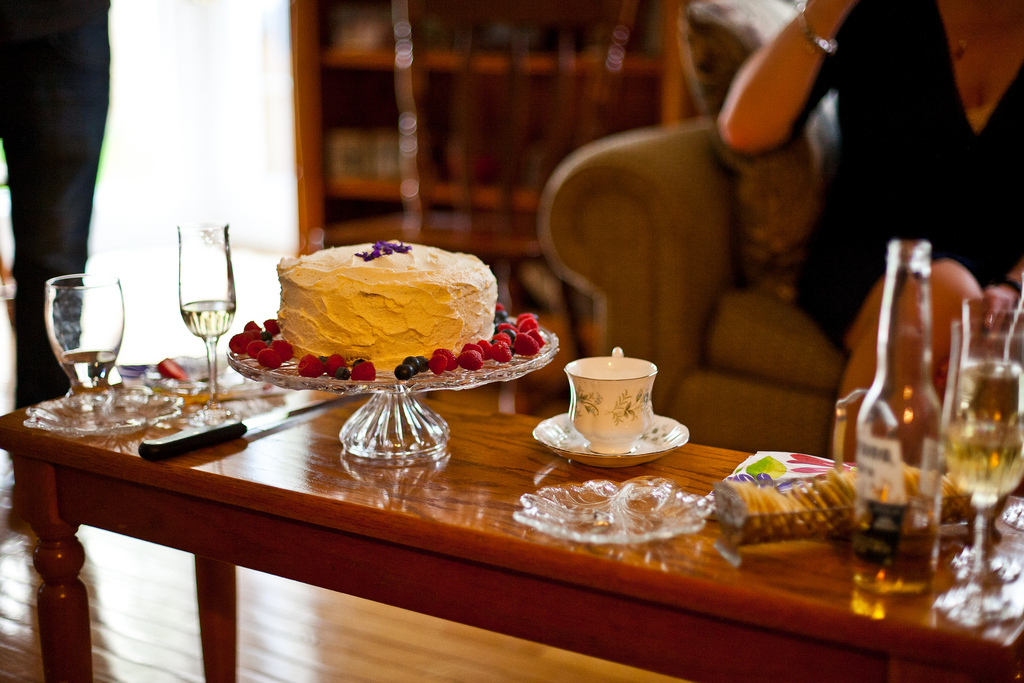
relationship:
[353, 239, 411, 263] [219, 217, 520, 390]
blueberries are attached to cake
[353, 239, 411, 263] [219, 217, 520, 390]
blueberries are on top of cake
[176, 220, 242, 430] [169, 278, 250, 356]
champegne flue has wine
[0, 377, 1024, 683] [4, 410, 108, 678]
coffee table has a foot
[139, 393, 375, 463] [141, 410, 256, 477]
knife has a handle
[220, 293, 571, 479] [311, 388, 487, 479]
cake plate has a base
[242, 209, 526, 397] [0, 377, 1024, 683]
cake on a coffee table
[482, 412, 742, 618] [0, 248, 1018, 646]
ashtray on a table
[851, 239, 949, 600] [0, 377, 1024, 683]
beer on a coffee table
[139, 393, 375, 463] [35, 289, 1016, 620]
knife on a table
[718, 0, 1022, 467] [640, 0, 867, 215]
person has an arm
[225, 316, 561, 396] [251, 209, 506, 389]
berries near cake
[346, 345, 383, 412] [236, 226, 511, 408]
raspberry around cake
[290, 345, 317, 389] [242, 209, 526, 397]
raspberry around cake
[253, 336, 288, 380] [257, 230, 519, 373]
raspberry around cake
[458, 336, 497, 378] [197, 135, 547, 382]
raspberry around cake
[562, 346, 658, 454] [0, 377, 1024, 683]
cup sitting on coffee table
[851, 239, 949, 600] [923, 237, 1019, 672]
beer next to champagne flute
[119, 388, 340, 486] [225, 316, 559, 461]
knife next to cake plate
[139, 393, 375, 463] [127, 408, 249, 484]
knife has a handle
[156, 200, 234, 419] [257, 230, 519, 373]
champegne flue next to cake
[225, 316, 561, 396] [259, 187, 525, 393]
berries surrounding cake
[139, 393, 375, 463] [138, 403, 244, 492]
knife has a handle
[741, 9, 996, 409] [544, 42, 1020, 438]
person sitting on top of sofa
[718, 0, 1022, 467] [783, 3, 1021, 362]
person wearing dress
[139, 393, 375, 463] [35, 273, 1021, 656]
knife on top of table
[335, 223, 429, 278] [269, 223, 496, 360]
blueberries are on top of cake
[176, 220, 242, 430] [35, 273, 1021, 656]
champegne flue on top of table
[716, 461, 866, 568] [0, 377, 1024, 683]
crackers are on top of coffee table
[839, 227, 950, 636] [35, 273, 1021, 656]
beer on top of table